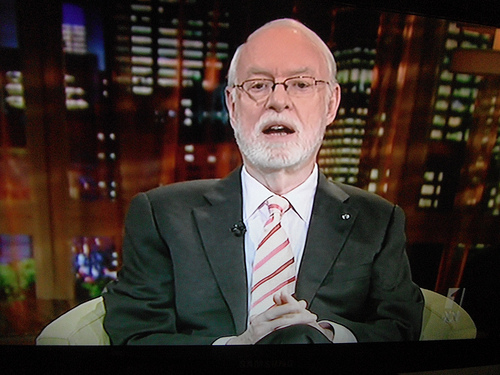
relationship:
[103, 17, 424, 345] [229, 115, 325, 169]
man has beard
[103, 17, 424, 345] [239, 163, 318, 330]
man wearing collared shirt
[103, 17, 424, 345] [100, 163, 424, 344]
man wearing suit jacket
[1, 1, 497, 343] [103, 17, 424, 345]
background behind man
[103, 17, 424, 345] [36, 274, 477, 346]
man sitting in chair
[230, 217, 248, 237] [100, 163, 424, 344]
microphone attached to suit jacket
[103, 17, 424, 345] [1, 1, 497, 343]
man seated in front of background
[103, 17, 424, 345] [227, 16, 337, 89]
man has hair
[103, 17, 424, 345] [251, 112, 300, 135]
man has mustache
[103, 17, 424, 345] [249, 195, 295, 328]
man wearing tie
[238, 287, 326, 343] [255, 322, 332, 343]
hands folded on knee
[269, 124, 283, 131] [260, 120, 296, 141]
upper teeth inside of mouth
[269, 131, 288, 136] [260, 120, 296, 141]
lower teeth inside of mouth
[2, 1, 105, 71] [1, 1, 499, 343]
sky behind buildings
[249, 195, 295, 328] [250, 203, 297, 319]
tie has stripes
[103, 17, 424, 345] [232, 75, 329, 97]
man wearing glasses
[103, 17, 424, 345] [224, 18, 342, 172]
man has head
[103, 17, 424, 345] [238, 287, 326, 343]
man clasping hands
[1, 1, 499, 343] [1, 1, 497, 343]
buildings in background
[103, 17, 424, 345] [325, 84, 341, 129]
man has ear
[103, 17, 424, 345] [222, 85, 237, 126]
man has ear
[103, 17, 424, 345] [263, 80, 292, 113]
man has nose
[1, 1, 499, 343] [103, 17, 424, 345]
buildings behind man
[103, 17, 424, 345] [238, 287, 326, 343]
man clasping h hands